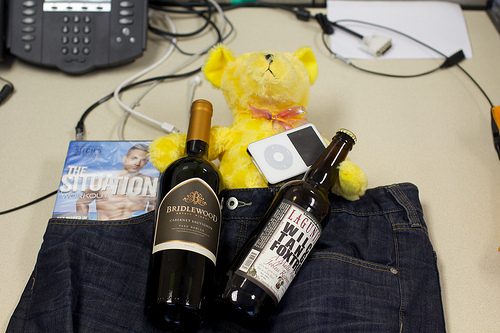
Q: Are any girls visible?
A: No, there are no girls.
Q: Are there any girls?
A: No, there are no girls.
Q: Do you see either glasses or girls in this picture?
A: No, there are no girls or glasses.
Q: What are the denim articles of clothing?
A: The clothing items are jeans.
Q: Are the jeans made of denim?
A: Yes, the jeans are made of denim.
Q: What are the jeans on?
A: The jeans are on the table.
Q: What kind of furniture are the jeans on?
A: The jeans are on the table.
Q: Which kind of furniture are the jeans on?
A: The jeans are on the table.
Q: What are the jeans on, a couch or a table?
A: The jeans are on a table.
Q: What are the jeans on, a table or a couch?
A: The jeans are on a table.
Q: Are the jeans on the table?
A: Yes, the jeans are on the table.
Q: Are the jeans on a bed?
A: No, the jeans are on the table.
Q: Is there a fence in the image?
A: No, there are no fences.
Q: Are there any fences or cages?
A: No, there are no fences or cages.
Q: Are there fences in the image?
A: No, there are no fences.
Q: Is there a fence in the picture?
A: No, there are no fences.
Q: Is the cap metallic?
A: Yes, the cap is metallic.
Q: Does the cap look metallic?
A: Yes, the cap is metallic.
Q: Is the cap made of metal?
A: Yes, the cap is made of metal.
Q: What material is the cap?
A: The cap is made of metal.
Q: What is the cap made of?
A: The cap is made of metal.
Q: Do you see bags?
A: No, there are no bags.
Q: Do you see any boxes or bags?
A: No, there are no bags or boxes.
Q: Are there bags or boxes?
A: No, there are no bags or boxes.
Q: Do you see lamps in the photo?
A: No, there are no lamps.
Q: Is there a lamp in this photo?
A: No, there are no lamps.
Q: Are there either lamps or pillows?
A: No, there are no lamps or pillows.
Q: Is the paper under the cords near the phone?
A: Yes, the paper is under the cords.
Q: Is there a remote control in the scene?
A: No, there are no remote controls.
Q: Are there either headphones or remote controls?
A: No, there are no remote controls or headphones.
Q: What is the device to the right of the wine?
A: The device is an ipod.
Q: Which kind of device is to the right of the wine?
A: The device is an ipod.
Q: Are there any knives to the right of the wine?
A: No, there is an ipod to the right of the wine.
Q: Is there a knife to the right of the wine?
A: No, there is an ipod to the right of the wine.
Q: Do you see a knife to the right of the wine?
A: No, there is an ipod to the right of the wine.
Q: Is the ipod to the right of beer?
A: No, the ipod is to the right of the wine.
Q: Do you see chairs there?
A: No, there are no chairs.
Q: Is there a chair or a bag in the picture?
A: No, there are no chairs or bags.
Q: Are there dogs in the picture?
A: No, there are no dogs.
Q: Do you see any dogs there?
A: No, there are no dogs.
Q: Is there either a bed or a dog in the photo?
A: No, there are no dogs or beds.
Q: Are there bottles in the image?
A: Yes, there is a bottle.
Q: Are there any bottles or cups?
A: Yes, there is a bottle.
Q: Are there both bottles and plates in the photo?
A: No, there is a bottle but no plates.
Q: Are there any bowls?
A: No, there are no bowls.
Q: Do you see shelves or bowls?
A: No, there are no bowls or shelves.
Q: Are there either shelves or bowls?
A: No, there are no bowls or shelves.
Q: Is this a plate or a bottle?
A: This is a bottle.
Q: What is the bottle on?
A: The bottle is on the table.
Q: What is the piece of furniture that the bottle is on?
A: The piece of furniture is a table.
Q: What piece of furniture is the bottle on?
A: The bottle is on the table.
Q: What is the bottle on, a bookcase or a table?
A: The bottle is on a table.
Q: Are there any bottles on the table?
A: Yes, there is a bottle on the table.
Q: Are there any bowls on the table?
A: No, there is a bottle on the table.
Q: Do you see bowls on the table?
A: No, there is a bottle on the table.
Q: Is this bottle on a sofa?
A: No, the bottle is on a table.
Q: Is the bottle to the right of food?
A: No, the bottle is to the right of the wine.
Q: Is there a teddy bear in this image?
A: Yes, there is a teddy bear.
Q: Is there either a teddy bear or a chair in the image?
A: Yes, there is a teddy bear.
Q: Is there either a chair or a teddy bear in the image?
A: Yes, there is a teddy bear.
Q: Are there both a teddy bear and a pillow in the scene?
A: No, there is a teddy bear but no pillows.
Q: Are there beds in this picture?
A: No, there are no beds.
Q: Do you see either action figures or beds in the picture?
A: No, there are no beds or action figures.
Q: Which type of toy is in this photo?
A: The toy is a teddy bear.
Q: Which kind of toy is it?
A: The toy is a teddy bear.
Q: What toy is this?
A: This is a teddy bear.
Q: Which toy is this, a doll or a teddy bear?
A: This is a teddy bear.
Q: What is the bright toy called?
A: The toy is a teddy bear.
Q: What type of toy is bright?
A: The toy is a teddy bear.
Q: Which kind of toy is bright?
A: The toy is a teddy bear.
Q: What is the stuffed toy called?
A: The toy is a teddy bear.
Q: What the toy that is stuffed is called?
A: The toy is a teddy bear.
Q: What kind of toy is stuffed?
A: The toy is a teddy bear.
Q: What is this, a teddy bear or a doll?
A: This is a teddy bear.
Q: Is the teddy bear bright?
A: Yes, the teddy bear is bright.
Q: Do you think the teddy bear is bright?
A: Yes, the teddy bear is bright.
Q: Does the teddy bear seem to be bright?
A: Yes, the teddy bear is bright.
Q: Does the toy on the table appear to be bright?
A: Yes, the teddy bear is bright.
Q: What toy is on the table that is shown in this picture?
A: The toy is a teddy bear.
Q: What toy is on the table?
A: The toy is a teddy bear.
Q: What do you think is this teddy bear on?
A: The teddy bear is on the table.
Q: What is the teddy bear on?
A: The teddy bear is on the table.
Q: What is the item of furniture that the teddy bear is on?
A: The piece of furniture is a table.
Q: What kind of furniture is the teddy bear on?
A: The teddy bear is on the table.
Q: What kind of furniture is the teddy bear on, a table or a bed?
A: The teddy bear is on a table.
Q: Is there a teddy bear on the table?
A: Yes, there is a teddy bear on the table.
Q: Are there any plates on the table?
A: No, there is a teddy bear on the table.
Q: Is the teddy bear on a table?
A: Yes, the teddy bear is on a table.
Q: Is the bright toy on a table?
A: Yes, the teddy bear is on a table.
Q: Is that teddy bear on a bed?
A: No, the teddy bear is on a table.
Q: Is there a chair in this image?
A: No, there are no chairs.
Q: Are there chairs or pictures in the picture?
A: No, there are no chairs or pictures.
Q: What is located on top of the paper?
A: The cable is on top of the paper.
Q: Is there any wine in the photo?
A: Yes, there is wine.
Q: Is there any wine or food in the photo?
A: Yes, there is wine.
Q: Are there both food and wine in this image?
A: No, there is wine but no food.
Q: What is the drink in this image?
A: The drink is wine.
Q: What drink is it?
A: The drink is wine.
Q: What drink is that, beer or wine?
A: This is wine.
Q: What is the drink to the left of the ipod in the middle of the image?
A: The drink is wine.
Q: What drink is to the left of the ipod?
A: The drink is wine.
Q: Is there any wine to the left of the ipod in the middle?
A: Yes, there is wine to the left of the ipod.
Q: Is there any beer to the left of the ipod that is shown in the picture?
A: No, there is wine to the left of the ipod.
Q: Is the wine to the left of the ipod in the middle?
A: Yes, the wine is to the left of the ipod.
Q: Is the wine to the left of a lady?
A: No, the wine is to the left of the ipod.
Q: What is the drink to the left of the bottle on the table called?
A: The drink is wine.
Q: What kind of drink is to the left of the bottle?
A: The drink is wine.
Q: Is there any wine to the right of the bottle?
A: No, the wine is to the left of the bottle.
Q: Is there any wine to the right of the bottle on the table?
A: No, the wine is to the left of the bottle.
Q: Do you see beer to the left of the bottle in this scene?
A: No, there is wine to the left of the bottle.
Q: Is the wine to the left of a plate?
A: No, the wine is to the left of the bottle.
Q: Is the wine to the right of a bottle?
A: No, the wine is to the left of a bottle.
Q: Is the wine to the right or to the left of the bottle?
A: The wine is to the left of the bottle.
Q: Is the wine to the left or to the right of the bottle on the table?
A: The wine is to the left of the bottle.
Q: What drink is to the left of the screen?
A: The drink is wine.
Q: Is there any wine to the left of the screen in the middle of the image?
A: Yes, there is wine to the left of the screen.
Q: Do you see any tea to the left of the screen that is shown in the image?
A: No, there is wine to the left of the screen.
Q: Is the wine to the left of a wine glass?
A: No, the wine is to the left of a screen.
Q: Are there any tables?
A: Yes, there is a table.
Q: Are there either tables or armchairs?
A: Yes, there is a table.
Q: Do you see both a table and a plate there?
A: No, there is a table but no plates.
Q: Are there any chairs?
A: No, there are no chairs.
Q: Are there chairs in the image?
A: No, there are no chairs.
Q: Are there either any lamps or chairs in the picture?
A: No, there are no chairs or lamps.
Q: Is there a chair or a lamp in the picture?
A: No, there are no chairs or lamps.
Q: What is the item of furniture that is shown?
A: The piece of furniture is a table.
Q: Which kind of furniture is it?
A: The piece of furniture is a table.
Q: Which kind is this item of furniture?
A: This is a table.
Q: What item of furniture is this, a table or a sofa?
A: This is a table.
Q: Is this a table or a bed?
A: This is a table.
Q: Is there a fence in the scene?
A: No, there are no fences.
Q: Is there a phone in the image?
A: Yes, there is a phone.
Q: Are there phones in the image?
A: Yes, there is a phone.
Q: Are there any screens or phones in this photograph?
A: Yes, there is a phone.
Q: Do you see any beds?
A: No, there are no beds.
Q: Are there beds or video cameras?
A: No, there are no beds or video cameras.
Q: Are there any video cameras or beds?
A: No, there are no beds or video cameras.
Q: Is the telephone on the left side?
A: Yes, the telephone is on the left of the image.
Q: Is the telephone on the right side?
A: No, the telephone is on the left of the image.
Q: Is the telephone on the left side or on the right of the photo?
A: The telephone is on the left of the image.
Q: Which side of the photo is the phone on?
A: The phone is on the left of the image.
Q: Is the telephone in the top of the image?
A: Yes, the telephone is in the top of the image.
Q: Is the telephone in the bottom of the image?
A: No, the telephone is in the top of the image.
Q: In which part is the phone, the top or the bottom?
A: The phone is in the top of the image.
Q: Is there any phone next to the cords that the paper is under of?
A: Yes, there is a phone next to the cables.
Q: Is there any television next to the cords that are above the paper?
A: No, there is a phone next to the cords.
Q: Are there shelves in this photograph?
A: No, there are no shelves.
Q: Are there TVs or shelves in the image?
A: No, there are no shelves or tvs.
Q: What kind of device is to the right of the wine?
A: The device is a screen.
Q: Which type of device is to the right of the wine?
A: The device is a screen.